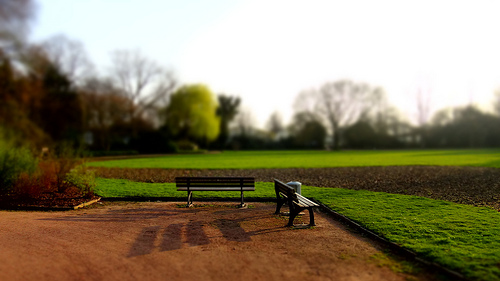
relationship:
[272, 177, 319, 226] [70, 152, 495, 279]
bench near grass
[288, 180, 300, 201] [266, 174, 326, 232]
trash can by bench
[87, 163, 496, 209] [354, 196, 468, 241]
dirt surrounded by grass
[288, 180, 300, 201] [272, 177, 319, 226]
trash can next to bench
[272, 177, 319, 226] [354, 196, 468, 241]
bench beside grass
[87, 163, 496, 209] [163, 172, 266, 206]
dirt behind bench